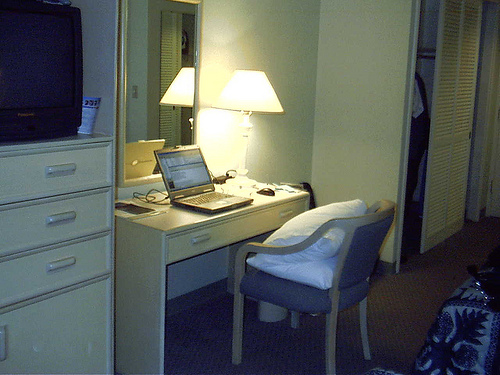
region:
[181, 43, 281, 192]
the table lamp is on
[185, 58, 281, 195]
the lamp is on the desk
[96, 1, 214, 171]
the mirror is reflecting the lamp shade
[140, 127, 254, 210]
lap top is open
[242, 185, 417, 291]
pillows in the chair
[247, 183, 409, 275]
the pillows are white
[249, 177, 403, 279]
the pillows are fluffy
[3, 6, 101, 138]
the tv is off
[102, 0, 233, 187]
the mirror is over the desk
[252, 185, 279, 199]
the mouse is black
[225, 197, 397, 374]
two pillow's on a chair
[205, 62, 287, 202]
a turned on table lamp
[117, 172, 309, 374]
a small wood desk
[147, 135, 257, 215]
a dark grey lap top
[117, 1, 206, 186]
a mirror hanging on the wall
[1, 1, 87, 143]
a turned off black tv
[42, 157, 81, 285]
three white handles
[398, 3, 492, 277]
a partialy open closet door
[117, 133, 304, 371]
a laptop sitting on a desk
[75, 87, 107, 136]
piece of paper showing tv channels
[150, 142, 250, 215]
a black open laptop computer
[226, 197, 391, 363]
a short blue chair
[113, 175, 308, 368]
a blonde wood desk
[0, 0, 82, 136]
a black TV set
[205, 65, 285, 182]
a table lamp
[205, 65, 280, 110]
a lit lamp shade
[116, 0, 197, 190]
a tall wall mirror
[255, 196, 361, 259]
a large white pillow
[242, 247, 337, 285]
a large white pillow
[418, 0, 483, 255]
an open closet door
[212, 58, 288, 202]
a lamp with a white shade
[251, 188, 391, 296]
a white pillow in a chair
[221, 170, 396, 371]
white and blue chair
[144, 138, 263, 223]
a laptop computer sitting on a desk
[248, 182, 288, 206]
a black computer mouse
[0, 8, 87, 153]
a black tv console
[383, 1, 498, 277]
a partially opened closet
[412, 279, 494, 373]
a blanket with snow flakes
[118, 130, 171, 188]
a computer's reflection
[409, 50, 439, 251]
clothes hanging in a closet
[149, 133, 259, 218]
laptop computer on a desk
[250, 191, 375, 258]
white pillow on chair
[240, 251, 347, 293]
white pillow on chair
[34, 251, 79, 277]
handle on a dresser drawer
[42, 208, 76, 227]
handle on a dresser drawer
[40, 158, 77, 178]
handle on a dresser drawer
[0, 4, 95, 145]
older style black television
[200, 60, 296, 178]
lamp with white shade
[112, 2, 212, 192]
mirror with white frame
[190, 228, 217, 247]
handle on a dresser drawer